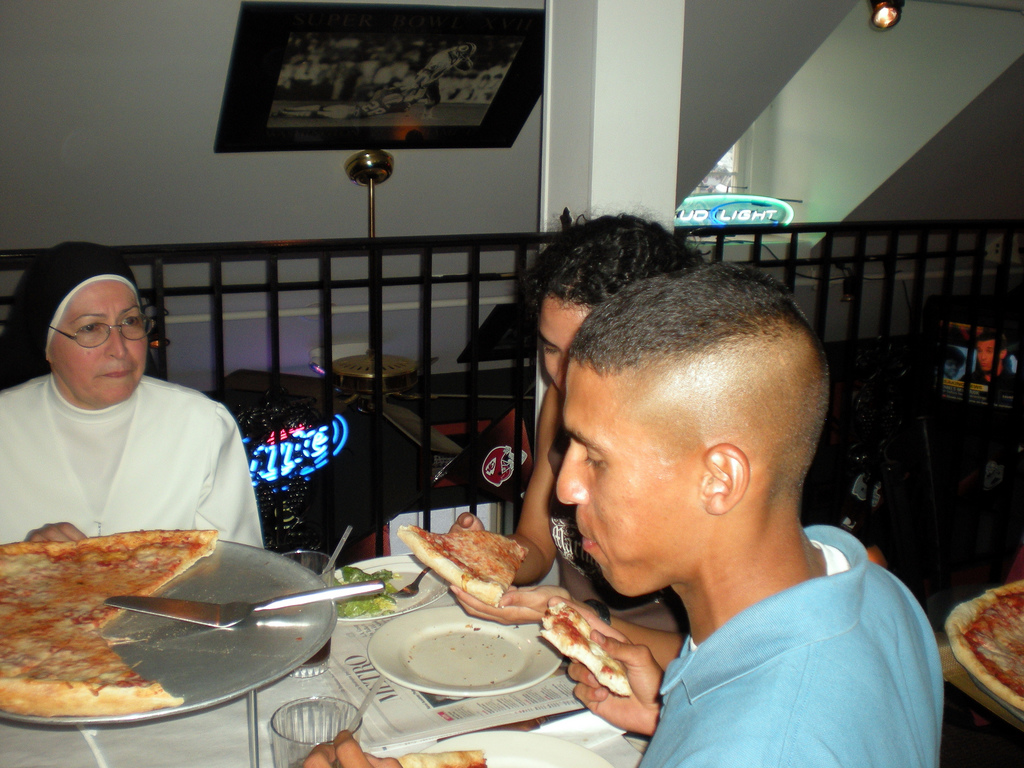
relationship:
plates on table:
[318, 554, 458, 624] [0, 554, 674, 754]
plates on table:
[364, 602, 579, 697] [0, 554, 674, 754]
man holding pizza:
[552, 269, 944, 764] [529, 585, 640, 697]